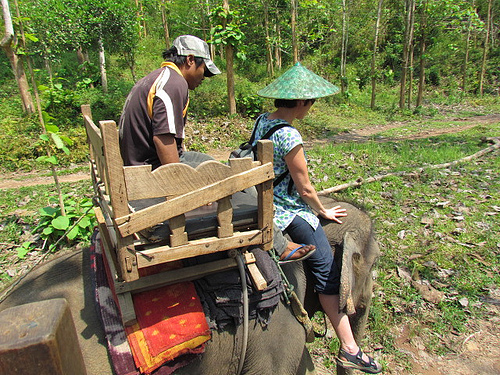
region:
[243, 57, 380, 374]
woman wearing a hat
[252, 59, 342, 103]
the hat is green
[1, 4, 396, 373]
people riding an elephant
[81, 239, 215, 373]
blanket on the elephant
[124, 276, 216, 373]
the blanket is red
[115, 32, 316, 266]
man is wearing a hat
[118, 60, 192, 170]
man's shirt is brown yellow and white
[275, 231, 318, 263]
man is wearing sandals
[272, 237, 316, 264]
the sandals are blue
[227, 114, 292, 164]
woman wearing a backpack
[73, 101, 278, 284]
wooden seat on top of an elephant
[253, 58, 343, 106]
green asian hat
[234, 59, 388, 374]
person riding on the elephant's head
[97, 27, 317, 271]
man sitting in the seat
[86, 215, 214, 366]
red and yellow blanket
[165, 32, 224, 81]
man's baseball cap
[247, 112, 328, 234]
woman's white and green top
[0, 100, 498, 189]
dirt path on the grass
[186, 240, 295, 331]
grey blanket on the elephant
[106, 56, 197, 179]
man's grey and yellow and white shirt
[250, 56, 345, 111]
a green hat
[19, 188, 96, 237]
a green plant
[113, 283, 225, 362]
red and orange cloth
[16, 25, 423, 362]
two people riding an elephant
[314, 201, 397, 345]
the head of an elephant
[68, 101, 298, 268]
a wooden chair on an elephant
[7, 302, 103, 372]
a wooden post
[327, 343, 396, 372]
sandals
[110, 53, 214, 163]
a brown and white striped shirt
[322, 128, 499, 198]
a log on the ground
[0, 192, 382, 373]
Elephant in the field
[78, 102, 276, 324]
Wood seat on the elephant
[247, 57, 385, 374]
Woman sitting on the elephant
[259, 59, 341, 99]
Bamboo hat on the woman's head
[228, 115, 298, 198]
Backpack on the woman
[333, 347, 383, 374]
Sandal on the woman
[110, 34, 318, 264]
Man sitting on the wood seat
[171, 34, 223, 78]
Hat on the man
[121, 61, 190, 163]
Shirt on the man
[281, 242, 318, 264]
Flip flop on the man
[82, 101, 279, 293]
a seat placed on top of an elephant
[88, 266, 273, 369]
blankets covering on top of a elephant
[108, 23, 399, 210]
two people riding on an elephant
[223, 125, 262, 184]
a person carrying a backpack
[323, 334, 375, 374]
a woman wearing black sandals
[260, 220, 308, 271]
a guy wearing flip flops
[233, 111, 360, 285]
a woman sitting on an elephants head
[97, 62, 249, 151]
a guy wearing a black and orange shirt